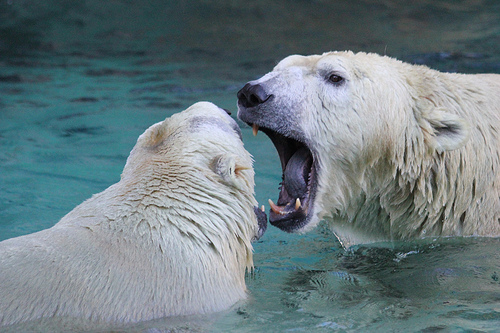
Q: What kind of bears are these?
A: Polar bears.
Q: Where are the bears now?
A: In the water.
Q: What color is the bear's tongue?
A: Black.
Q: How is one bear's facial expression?
A: Mouth wide open.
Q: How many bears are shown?
A: 2.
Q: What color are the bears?
A: White.